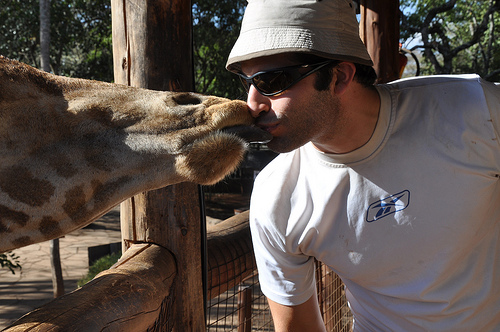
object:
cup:
[11, 52, 248, 259]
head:
[0, 67, 255, 244]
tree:
[389, 5, 499, 72]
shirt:
[248, 75, 498, 332]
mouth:
[260, 122, 280, 132]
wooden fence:
[1, 208, 248, 330]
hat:
[222, 0, 377, 73]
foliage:
[165, 16, 252, 119]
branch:
[421, 0, 498, 74]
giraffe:
[0, 58, 251, 256]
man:
[248, 0, 497, 332]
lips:
[265, 127, 279, 132]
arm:
[248, 178, 329, 329]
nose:
[247, 87, 270, 118]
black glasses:
[239, 59, 338, 96]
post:
[111, 2, 215, 331]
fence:
[0, 208, 354, 332]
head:
[233, 0, 381, 154]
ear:
[332, 61, 356, 95]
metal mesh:
[208, 237, 349, 330]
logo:
[367, 189, 410, 223]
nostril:
[172, 94, 202, 105]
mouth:
[219, 110, 272, 147]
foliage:
[6, 3, 111, 64]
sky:
[0, 1, 499, 78]